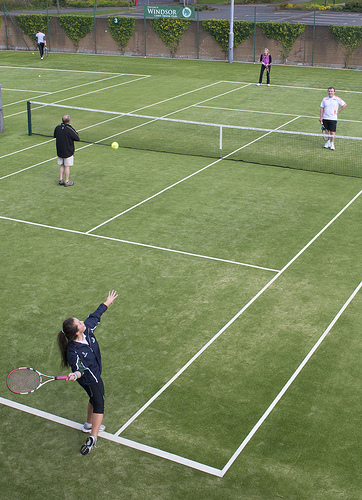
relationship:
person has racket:
[56, 288, 120, 458] [6, 365, 68, 397]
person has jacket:
[52, 112, 80, 189] [52, 124, 80, 158]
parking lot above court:
[2, 1, 360, 28] [0, 49, 362, 498]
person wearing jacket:
[56, 288, 120, 458] [65, 301, 109, 383]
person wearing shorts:
[317, 85, 346, 149] [322, 118, 338, 132]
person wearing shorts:
[52, 112, 80, 189] [55, 153, 76, 166]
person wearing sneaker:
[56, 288, 120, 458] [80, 436, 98, 458]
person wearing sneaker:
[56, 288, 120, 458] [82, 423, 107, 433]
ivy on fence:
[17, 14, 51, 40] [0, 0, 361, 69]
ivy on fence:
[56, 13, 94, 47] [0, 0, 361, 69]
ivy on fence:
[106, 16, 136, 50] [0, 0, 361, 69]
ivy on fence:
[147, 17, 189, 54] [0, 0, 361, 69]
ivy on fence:
[200, 17, 253, 55] [0, 0, 361, 69]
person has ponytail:
[56, 288, 120, 458] [56, 327, 71, 371]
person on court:
[34, 27, 46, 59] [0, 49, 362, 498]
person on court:
[255, 47, 273, 87] [0, 49, 362, 498]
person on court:
[317, 85, 346, 149] [0, 49, 362, 498]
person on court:
[52, 112, 80, 189] [0, 49, 362, 498]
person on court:
[56, 288, 120, 458] [0, 49, 362, 498]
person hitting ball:
[56, 288, 120, 458] [108, 140, 120, 151]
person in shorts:
[317, 85, 346, 149] [322, 118, 338, 132]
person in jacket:
[52, 112, 80, 189] [52, 124, 80, 158]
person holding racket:
[56, 288, 120, 458] [6, 365, 68, 397]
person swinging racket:
[56, 288, 120, 458] [6, 365, 68, 397]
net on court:
[26, 99, 362, 180] [0, 49, 362, 498]